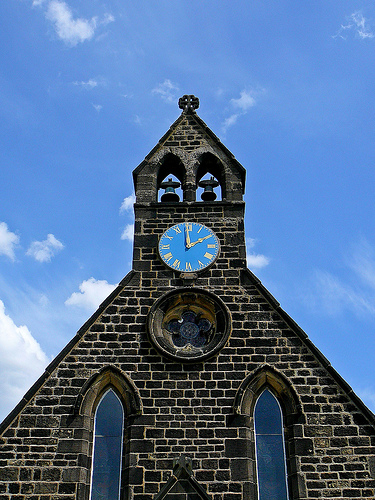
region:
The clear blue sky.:
[287, 70, 372, 195]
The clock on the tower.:
[157, 222, 218, 273]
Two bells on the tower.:
[161, 174, 222, 206]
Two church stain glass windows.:
[74, 365, 322, 498]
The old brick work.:
[148, 378, 226, 461]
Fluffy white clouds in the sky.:
[1, 221, 26, 395]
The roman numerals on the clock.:
[165, 251, 213, 266]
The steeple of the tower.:
[178, 90, 201, 111]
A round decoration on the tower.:
[148, 287, 234, 360]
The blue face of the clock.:
[180, 252, 199, 258]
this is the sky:
[230, 6, 321, 97]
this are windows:
[229, 364, 314, 497]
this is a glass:
[96, 400, 120, 496]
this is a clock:
[154, 221, 217, 276]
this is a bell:
[195, 171, 220, 202]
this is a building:
[0, 88, 366, 484]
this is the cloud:
[0, 323, 28, 356]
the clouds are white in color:
[1, 338, 38, 368]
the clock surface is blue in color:
[157, 216, 218, 282]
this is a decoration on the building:
[145, 286, 238, 364]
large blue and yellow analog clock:
[153, 217, 225, 279]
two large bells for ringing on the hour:
[153, 160, 229, 215]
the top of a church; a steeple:
[111, 95, 264, 277]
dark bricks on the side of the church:
[149, 379, 225, 429]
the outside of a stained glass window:
[142, 281, 233, 361]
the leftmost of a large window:
[226, 364, 297, 495]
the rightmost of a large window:
[87, 361, 141, 493]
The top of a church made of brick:
[5, 206, 370, 487]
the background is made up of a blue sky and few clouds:
[1, 5, 361, 98]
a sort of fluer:
[175, 91, 200, 111]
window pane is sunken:
[143, 274, 232, 378]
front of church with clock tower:
[40, 150, 342, 447]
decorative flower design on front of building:
[143, 283, 234, 364]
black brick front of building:
[157, 378, 212, 456]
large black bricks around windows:
[210, 391, 257, 487]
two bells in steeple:
[135, 144, 248, 219]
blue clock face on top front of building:
[151, 215, 222, 283]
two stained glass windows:
[48, 364, 322, 490]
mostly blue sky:
[25, 165, 127, 353]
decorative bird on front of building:
[151, 447, 221, 493]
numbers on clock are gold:
[161, 242, 200, 272]